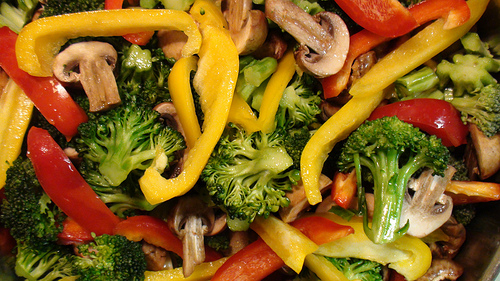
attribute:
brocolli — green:
[367, 124, 424, 217]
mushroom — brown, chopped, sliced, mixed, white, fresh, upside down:
[266, 0, 360, 74]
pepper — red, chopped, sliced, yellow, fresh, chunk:
[379, 107, 473, 148]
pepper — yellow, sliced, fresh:
[28, 10, 216, 62]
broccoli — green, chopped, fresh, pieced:
[212, 124, 338, 203]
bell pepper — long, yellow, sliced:
[171, 17, 230, 189]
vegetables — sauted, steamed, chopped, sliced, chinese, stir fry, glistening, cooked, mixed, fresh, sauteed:
[84, 59, 499, 263]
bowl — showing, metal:
[458, 206, 494, 279]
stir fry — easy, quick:
[171, 49, 367, 127]